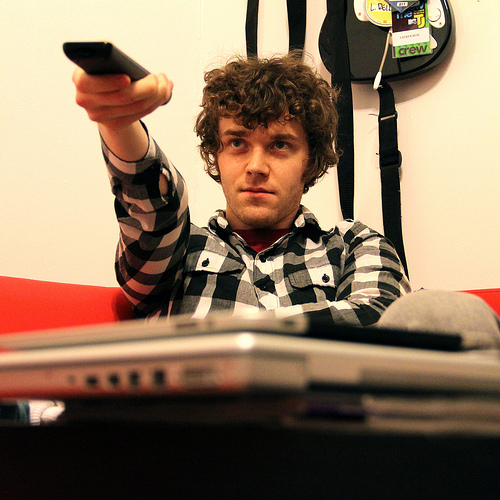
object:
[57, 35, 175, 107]
control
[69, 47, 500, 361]
man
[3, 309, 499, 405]
laptop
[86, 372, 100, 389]
hole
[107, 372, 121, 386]
hole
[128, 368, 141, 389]
hole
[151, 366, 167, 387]
hole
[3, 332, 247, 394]
side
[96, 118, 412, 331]
shirt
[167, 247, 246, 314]
pocket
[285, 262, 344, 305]
pocket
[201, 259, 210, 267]
button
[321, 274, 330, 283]
button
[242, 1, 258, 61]
strap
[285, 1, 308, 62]
strap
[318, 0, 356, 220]
strap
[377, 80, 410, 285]
strap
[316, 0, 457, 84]
guitar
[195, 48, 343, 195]
hair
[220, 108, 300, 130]
forehead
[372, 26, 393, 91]
bar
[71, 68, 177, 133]
hand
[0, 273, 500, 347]
couch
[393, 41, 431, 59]
paper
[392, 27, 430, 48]
paper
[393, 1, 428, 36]
paper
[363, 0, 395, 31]
paper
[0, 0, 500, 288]
wall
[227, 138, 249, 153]
eye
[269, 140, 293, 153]
eye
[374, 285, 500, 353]
pants